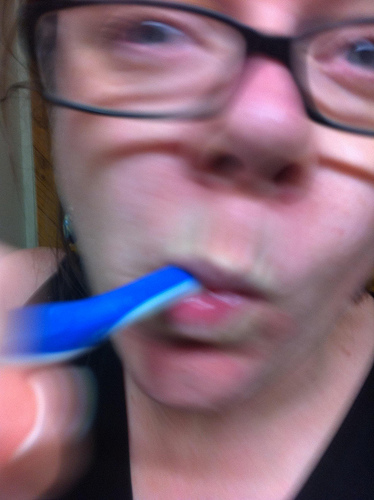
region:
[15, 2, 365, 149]
person wearing black eyeglass frames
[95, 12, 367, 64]
small, dark grey eyes peering out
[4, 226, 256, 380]
toothbrush partially in mouth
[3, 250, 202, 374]
light and dark blue handle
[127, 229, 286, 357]
small lips puckered together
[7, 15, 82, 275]
black hairs sticking out on side of head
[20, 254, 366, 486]
person wearing black top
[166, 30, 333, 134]
reddish nose under eyeglass bridge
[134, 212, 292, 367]
edges of lips are cream colored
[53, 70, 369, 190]
shadow of eyeglasses across face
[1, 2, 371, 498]
a woman brushing her teeth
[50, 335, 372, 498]
a black shirt on a woman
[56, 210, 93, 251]
an earring on a woman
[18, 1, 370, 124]
glasses on a woman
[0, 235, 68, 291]
a woman's bare shoulder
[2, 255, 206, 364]
fingers holding a blue toothbrush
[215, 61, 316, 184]
a woman's nose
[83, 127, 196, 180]
the shadow of glasses on a cheek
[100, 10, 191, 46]
an eye behind glasses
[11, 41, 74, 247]
a doorway behind a woman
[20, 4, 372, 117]
this girl wears glasses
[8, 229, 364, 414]
the girl is brushing her teeth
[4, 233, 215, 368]
the toothbrush is blue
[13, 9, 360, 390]
the picture is blurry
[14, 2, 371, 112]
the glasses are rectangular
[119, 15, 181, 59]
the girl's eyes are a light color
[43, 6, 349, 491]
the girl's face is red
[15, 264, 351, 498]
the girl is wearing a black shirt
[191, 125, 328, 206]
the girl's nose is clean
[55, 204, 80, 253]
the girl is wearing earrings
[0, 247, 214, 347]
the woman's toothbrush is blue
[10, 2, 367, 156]
the woman is wearing glasses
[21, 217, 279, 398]
the toothbrush is in the woman's mouth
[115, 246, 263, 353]
the woman's mouth is wet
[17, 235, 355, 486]
the woman is wearing a black shirt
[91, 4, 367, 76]
the woman has blue eyes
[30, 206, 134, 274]
the woman is wearing earrings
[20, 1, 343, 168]
the glasses are sitting on the woman's nose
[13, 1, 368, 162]
the glasses are black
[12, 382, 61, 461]
the woman's nail is white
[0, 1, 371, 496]
a woman with a toothbrush in her mouth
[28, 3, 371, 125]
a woman's eyeglasses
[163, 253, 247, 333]
a woman's lips pursed around a toothbrush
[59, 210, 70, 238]
a woman's earring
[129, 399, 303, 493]
a woman's neck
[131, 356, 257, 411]
a woman's chin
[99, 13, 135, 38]
a woman's eyelashes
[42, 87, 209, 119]
the rim of a woman's glasses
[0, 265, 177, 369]
a toothbrush